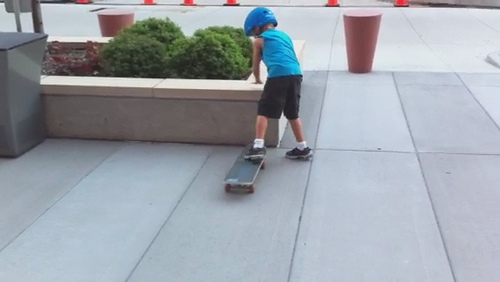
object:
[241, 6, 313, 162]
child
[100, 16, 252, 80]
bushes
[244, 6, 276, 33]
helmet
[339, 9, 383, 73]
pot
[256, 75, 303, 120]
shorts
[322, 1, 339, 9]
safety cone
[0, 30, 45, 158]
garbage can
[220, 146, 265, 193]
skateboard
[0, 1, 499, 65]
sidewalk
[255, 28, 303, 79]
tank top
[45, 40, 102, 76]
raise bed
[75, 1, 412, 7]
traffic cones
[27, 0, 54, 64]
trunk of tree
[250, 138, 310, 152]
socks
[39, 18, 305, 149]
planter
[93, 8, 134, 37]
pot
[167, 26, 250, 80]
bush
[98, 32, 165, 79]
bush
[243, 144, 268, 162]
foot